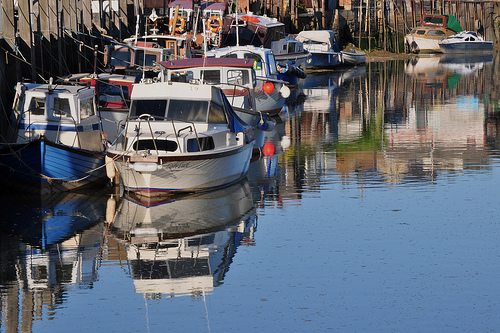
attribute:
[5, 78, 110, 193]
boat — white, blue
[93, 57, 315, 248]
boat — White 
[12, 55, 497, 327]
water — murky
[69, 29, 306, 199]
boat — white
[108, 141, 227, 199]
front — steamlined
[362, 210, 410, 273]
water — calm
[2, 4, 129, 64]
posts — wood, black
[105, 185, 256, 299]
reflection — boat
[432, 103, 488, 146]
reflection — wall, brick, tan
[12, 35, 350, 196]
boats — numberous